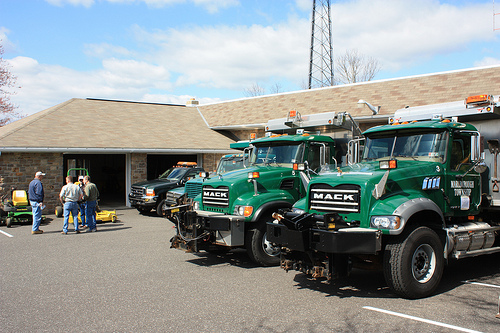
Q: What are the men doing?
A: Standing in a group.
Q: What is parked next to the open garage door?
A: A truck.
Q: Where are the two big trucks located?
A: Infront of the building.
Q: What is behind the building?
A: A metal tower.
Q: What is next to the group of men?
A: A couple of lawn mowers.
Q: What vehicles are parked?
A: Trucks.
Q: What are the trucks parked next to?
A: A building.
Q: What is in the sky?
A: Clouds.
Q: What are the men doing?
A: Talking.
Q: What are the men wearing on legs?
A: Jeans.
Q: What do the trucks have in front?
A: Towing attachments.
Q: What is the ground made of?
A: Concrete.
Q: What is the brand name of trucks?
A: Mack.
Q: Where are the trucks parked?
A: In front of the building.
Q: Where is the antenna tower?
A: Behind the building.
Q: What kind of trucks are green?
A: Dump trucks.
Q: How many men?
A: Four.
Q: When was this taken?
A: Day time.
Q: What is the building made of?
A: Brick.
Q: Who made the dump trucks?
A: Mack.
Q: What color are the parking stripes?
A: White.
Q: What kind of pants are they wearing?
A: Jeans.